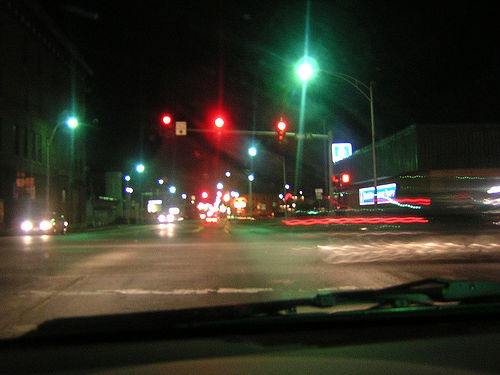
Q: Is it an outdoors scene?
A: Yes, it is outdoors.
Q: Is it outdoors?
A: Yes, it is outdoors.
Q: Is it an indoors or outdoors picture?
A: It is outdoors.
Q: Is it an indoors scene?
A: No, it is outdoors.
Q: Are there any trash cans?
A: No, there are no trash cans.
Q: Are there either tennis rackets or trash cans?
A: No, there are no trash cans or tennis rackets.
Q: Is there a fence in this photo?
A: No, there are no fences.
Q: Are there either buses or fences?
A: No, there are no fences or buses.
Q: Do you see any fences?
A: No, there are no fences.